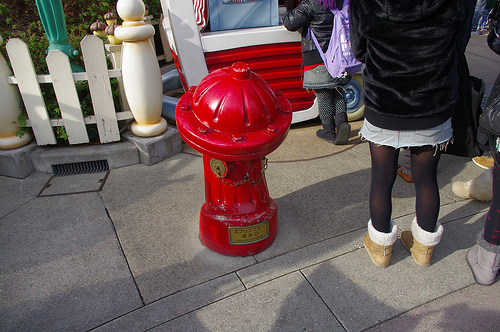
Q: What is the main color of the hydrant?
A: Red.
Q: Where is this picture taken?
A: Sidewalk.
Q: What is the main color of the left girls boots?
A: Brown.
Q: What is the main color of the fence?
A: White.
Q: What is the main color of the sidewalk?
A: Gray.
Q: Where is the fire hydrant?
A: On the sidewalk.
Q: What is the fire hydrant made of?
A: Metal.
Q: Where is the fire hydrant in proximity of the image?
A: Center.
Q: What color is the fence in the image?
A: White.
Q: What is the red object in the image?
A: Fire hydrant.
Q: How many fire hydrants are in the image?
A: One.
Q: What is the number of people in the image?
A: Three.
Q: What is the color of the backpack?
A: Purple.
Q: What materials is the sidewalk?
A: Cement.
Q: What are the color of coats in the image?
A: Black.